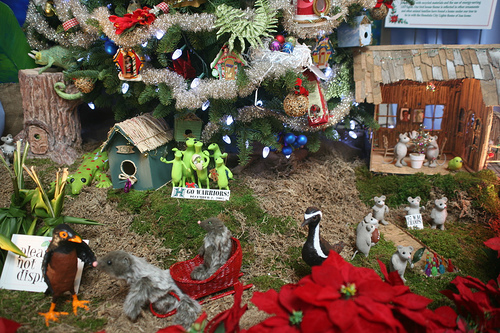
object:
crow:
[37, 224, 97, 327]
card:
[0, 233, 90, 296]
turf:
[140, 248, 255, 286]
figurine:
[208, 157, 236, 192]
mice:
[0, 133, 23, 166]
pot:
[409, 152, 425, 169]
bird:
[301, 206, 346, 269]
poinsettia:
[252, 253, 458, 332]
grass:
[180, 229, 197, 239]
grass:
[426, 234, 455, 245]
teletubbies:
[112, 46, 145, 82]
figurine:
[390, 243, 425, 285]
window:
[422, 104, 445, 131]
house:
[352, 43, 500, 177]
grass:
[207, 202, 218, 210]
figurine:
[172, 136, 211, 189]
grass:
[168, 203, 198, 218]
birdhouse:
[334, 13, 376, 48]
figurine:
[37, 225, 99, 321]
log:
[12, 66, 93, 167]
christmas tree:
[23, 0, 414, 165]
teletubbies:
[401, 188, 448, 231]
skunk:
[190, 217, 234, 281]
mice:
[422, 135, 447, 168]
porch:
[366, 140, 474, 177]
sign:
[171, 187, 231, 201]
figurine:
[430, 197, 448, 230]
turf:
[15, 137, 74, 322]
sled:
[149, 237, 253, 318]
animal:
[91, 250, 204, 327]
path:
[377, 224, 462, 277]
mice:
[349, 222, 378, 261]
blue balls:
[281, 133, 308, 155]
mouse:
[426, 195, 448, 230]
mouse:
[400, 191, 423, 226]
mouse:
[368, 195, 390, 225]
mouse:
[381, 132, 411, 167]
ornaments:
[295, 132, 307, 149]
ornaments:
[279, 127, 296, 150]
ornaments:
[278, 141, 296, 157]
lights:
[170, 43, 190, 61]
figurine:
[208, 143, 228, 168]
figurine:
[189, 140, 210, 189]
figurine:
[160, 148, 191, 188]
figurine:
[422, 134, 447, 168]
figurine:
[403, 196, 425, 227]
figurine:
[381, 132, 410, 168]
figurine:
[372, 195, 390, 226]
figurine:
[351, 223, 377, 260]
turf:
[416, 232, 456, 241]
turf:
[169, 202, 227, 211]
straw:
[310, 177, 332, 194]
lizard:
[47, 142, 114, 195]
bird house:
[99, 111, 180, 191]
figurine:
[48, 142, 113, 194]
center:
[325, 273, 360, 303]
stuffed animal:
[89, 248, 201, 328]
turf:
[26, 312, 116, 330]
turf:
[263, 224, 299, 277]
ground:
[2, 180, 496, 332]